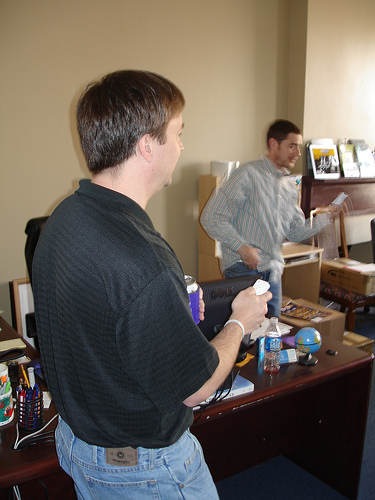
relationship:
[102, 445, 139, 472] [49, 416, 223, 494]
logo on jeans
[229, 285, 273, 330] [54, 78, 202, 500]
hand on man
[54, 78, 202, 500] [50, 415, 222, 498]
man wearing blue jeans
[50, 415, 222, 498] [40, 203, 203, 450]
blue jeans wearing shirt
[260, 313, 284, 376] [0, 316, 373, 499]
bottle on desk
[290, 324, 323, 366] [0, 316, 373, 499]
globe on desk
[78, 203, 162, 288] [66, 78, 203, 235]
shirt on man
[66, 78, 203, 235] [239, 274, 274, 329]
man playing video game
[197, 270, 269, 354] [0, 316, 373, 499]
monitor on desk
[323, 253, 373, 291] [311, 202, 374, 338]
box on chair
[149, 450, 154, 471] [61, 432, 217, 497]
loop on blue jeans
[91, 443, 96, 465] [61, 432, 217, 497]
loop on blue jeans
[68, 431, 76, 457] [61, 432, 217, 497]
belt loop on blue jeans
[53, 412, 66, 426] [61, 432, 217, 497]
belt loop on blue jeans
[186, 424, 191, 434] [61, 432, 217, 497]
loop on blue jeans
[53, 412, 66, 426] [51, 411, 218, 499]
belt loop on jeans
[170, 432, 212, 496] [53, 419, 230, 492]
pocket on jeans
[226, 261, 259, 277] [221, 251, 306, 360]
pocket on jeans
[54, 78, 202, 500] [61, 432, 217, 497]
man wearing blue jeans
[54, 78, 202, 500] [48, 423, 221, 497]
man wearing jeans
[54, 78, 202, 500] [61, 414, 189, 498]
man wearing blue jeans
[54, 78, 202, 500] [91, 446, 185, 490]
man wearing jeans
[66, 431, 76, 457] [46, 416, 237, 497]
belt loop on jeans